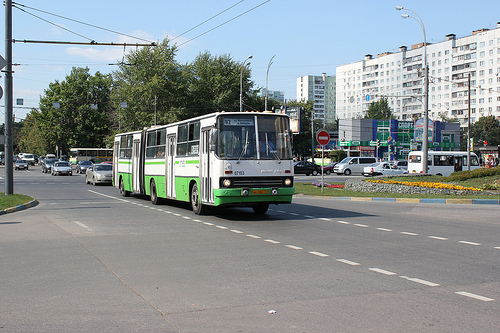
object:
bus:
[112, 111, 296, 216]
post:
[3, 1, 16, 193]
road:
[0, 213, 499, 322]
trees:
[22, 39, 308, 157]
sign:
[316, 126, 331, 194]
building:
[334, 30, 498, 153]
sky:
[2, 1, 499, 63]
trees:
[27, 41, 314, 113]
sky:
[0, 0, 499, 123]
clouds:
[69, 30, 186, 68]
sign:
[313, 129, 331, 148]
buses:
[115, 111, 296, 216]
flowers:
[317, 178, 488, 193]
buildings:
[295, 29, 499, 171]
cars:
[17, 145, 114, 184]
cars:
[294, 150, 483, 176]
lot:
[320, 172, 498, 199]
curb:
[14, 180, 86, 185]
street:
[0, 172, 498, 328]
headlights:
[220, 175, 294, 186]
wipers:
[236, 130, 282, 161]